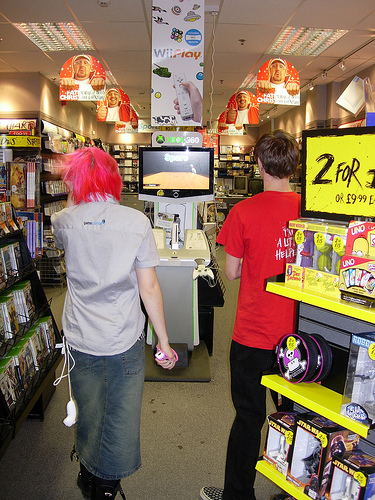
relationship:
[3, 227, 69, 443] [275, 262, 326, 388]
games stacked on shelf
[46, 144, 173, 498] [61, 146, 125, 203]
girl with hair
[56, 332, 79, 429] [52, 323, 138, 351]
controller hanging from girl's hips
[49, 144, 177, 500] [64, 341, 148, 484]
girl wearing skirt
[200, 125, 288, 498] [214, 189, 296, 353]
man wearing red shirt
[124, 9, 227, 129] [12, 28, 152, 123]
banner hanging from ceiling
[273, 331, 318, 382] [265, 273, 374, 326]
purse sitting on shelf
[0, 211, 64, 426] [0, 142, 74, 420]
video games line shelves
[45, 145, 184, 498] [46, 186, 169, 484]
person wearing clothing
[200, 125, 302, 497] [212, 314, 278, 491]
man wearing pants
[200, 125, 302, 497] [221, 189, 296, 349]
man wearing red shirt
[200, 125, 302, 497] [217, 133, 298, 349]
man wearing person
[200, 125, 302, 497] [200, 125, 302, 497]
man wearing man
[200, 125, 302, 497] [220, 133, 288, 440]
man wearing person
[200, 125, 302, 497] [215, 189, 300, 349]
man wearing red shirt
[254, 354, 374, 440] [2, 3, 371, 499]
shelf in store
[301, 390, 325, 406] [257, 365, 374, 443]
part of a shelf